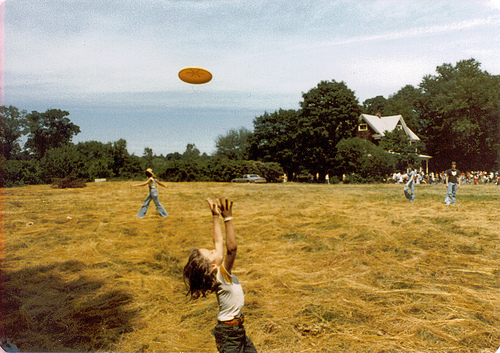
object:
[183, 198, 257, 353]
child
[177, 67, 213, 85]
frisbee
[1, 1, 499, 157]
sky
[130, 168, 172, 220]
people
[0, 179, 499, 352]
field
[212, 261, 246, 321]
shirt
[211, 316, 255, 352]
shorts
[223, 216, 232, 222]
wristband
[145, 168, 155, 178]
hat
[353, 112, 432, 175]
house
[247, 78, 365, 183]
trees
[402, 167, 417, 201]
guy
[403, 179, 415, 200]
jeans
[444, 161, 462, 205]
guy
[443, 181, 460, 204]
jeans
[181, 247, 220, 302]
hair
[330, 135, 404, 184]
trees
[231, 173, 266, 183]
car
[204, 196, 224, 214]
hands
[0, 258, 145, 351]
shadow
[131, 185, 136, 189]
hand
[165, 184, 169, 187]
hand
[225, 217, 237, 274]
air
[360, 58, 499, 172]
trees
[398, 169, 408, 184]
people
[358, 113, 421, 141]
roof